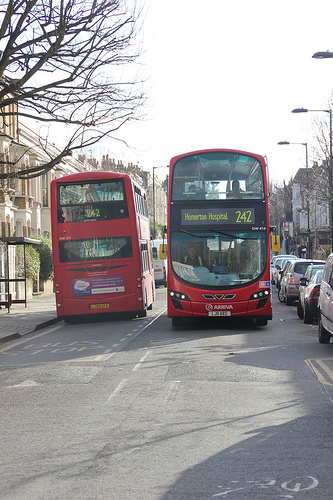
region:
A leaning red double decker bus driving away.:
[50, 170, 156, 321]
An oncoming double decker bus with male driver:
[163, 148, 271, 326]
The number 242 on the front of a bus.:
[235, 209, 252, 221]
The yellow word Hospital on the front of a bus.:
[207, 211, 228, 221]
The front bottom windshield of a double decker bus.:
[167, 228, 266, 287]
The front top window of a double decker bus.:
[171, 149, 263, 201]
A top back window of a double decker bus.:
[56, 178, 128, 221]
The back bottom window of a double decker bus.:
[55, 237, 133, 261]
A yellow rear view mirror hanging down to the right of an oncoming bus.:
[270, 233, 280, 252]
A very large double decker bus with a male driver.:
[163, 149, 272, 325]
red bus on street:
[165, 148, 273, 328]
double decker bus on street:
[49, 171, 156, 317]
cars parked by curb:
[272, 251, 331, 339]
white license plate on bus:
[208, 310, 230, 316]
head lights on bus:
[168, 291, 186, 299]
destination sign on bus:
[181, 208, 253, 224]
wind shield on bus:
[171, 230, 266, 283]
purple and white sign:
[70, 275, 124, 294]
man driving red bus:
[183, 245, 202, 267]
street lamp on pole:
[277, 138, 308, 256]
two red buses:
[45, 143, 274, 322]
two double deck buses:
[49, 148, 278, 317]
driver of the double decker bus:
[180, 245, 209, 281]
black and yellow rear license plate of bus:
[86, 302, 110, 314]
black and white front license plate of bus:
[208, 309, 231, 317]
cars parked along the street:
[273, 247, 332, 348]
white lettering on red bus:
[202, 300, 237, 310]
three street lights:
[267, 23, 332, 269]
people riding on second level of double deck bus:
[180, 166, 260, 199]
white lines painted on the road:
[89, 313, 169, 422]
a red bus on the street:
[164, 143, 274, 322]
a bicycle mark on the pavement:
[212, 469, 322, 498]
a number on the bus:
[235, 206, 256, 226]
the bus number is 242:
[234, 204, 257, 224]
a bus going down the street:
[44, 164, 162, 316]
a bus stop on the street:
[22, 332, 105, 360]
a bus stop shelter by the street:
[4, 229, 42, 311]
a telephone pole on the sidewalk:
[275, 136, 314, 252]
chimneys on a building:
[78, 146, 146, 176]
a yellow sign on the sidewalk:
[269, 233, 289, 254]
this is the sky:
[170, 19, 257, 126]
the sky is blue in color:
[163, 105, 235, 136]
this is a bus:
[166, 166, 268, 354]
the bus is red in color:
[189, 290, 209, 307]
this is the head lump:
[161, 290, 183, 299]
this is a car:
[293, 258, 321, 314]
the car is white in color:
[319, 288, 332, 302]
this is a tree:
[24, 245, 42, 277]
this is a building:
[13, 189, 51, 236]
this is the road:
[73, 356, 268, 484]